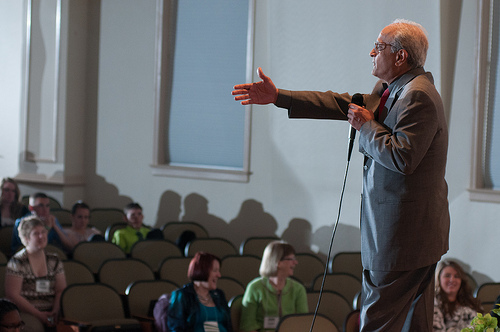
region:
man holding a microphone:
[231, 18, 452, 330]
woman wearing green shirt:
[239, 239, 311, 329]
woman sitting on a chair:
[151, 251, 233, 329]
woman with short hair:
[3, 213, 70, 329]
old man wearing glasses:
[230, 21, 454, 330]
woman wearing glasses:
[237, 237, 308, 329]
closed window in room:
[147, 0, 254, 185]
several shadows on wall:
[152, 189, 360, 255]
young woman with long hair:
[432, 257, 484, 329]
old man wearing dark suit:
[230, 17, 453, 329]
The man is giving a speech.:
[225, 15, 475, 329]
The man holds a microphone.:
[322, 84, 388, 182]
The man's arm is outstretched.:
[216, 55, 393, 136]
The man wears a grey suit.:
[237, 60, 469, 330]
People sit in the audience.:
[141, 221, 328, 329]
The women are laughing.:
[170, 227, 317, 299]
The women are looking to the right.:
[170, 221, 320, 303]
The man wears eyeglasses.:
[362, 30, 409, 58]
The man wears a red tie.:
[345, 77, 395, 141]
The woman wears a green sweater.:
[230, 268, 313, 329]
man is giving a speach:
[220, 19, 462, 327]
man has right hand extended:
[230, 14, 461, 325]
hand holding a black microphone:
[336, 85, 379, 168]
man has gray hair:
[319, 6, 464, 126]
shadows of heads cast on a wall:
[154, 176, 354, 241]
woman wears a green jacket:
[237, 230, 318, 330]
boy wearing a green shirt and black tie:
[104, 196, 161, 253]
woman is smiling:
[436, 256, 478, 326]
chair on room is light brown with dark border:
[93, 247, 158, 293]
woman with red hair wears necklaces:
[159, 234, 240, 326]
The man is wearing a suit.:
[239, 15, 451, 329]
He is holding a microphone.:
[327, 83, 375, 160]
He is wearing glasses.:
[346, 15, 443, 88]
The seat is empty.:
[80, 253, 146, 320]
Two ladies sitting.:
[179, 255, 314, 322]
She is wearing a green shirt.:
[246, 232, 308, 324]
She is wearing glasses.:
[268, 237, 303, 274]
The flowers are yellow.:
[461, 302, 498, 330]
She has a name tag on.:
[5, 207, 76, 303]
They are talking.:
[154, 239, 301, 329]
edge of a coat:
[375, 254, 412, 282]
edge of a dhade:
[273, 205, 313, 244]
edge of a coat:
[349, 205, 371, 246]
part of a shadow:
[212, 197, 238, 227]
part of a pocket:
[379, 187, 399, 204]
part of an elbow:
[380, 150, 430, 247]